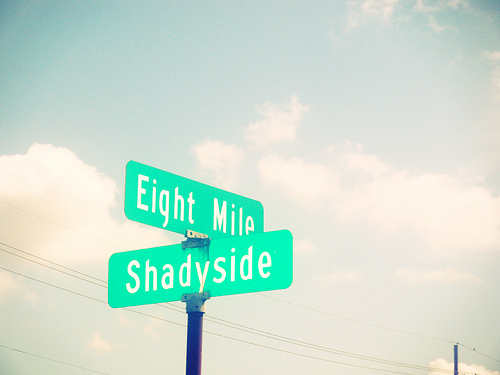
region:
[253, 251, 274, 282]
white letter on a sign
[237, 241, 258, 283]
white letter on a sign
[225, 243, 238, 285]
white letter on a sign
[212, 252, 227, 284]
white letter on a sign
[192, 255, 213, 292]
white letter on a sign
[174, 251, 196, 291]
white letter on a sign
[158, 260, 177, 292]
white letter on a sign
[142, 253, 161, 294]
white letter on a sign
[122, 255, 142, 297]
white letter on a sign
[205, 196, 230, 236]
white letter on a sign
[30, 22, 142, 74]
this is the sky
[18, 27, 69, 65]
the sky is blue in color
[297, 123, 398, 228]
the sky has clouds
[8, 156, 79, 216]
the clouds are white in color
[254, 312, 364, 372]
these are some wires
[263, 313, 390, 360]
the wires are thin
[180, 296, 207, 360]
this is a pole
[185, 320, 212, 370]
the pole is metallic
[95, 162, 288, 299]
these are two street signs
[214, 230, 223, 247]
the signs are green in color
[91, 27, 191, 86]
this is the sky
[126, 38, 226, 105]
the sky is bue in color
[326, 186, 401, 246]
these are the clouds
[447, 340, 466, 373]
this is a pole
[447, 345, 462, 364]
the pole is blue in color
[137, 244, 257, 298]
this is a signpost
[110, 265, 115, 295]
the signpost is bue in color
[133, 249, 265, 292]
this is a writing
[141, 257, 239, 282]
the writing is in white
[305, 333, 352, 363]
this is the wire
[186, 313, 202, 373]
blue metal pole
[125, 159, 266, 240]
green street sign perpendicular to street sign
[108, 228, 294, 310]
street sign under street sign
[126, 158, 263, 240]
street sign on top of street sign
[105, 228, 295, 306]
street sign mounted on top of pole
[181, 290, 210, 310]
bracket attached to street sign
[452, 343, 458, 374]
utility pole in front of the sky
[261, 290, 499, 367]
black wire attached to utility pole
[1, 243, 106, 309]
wires behind street sign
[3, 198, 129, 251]
wire above wire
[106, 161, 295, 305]
street signs are green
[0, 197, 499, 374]
power lines run behind street signs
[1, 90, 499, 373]
large white clouds in the sky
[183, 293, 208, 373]
a large metal pole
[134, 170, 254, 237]
Top sign says Eight Mile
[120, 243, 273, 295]
Bottom sign says ShadySide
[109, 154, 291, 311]
two street signs are shown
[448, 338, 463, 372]
power line has line seperater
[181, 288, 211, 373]
only one pole holds both street signs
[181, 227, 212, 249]
metal clips seperating street signs